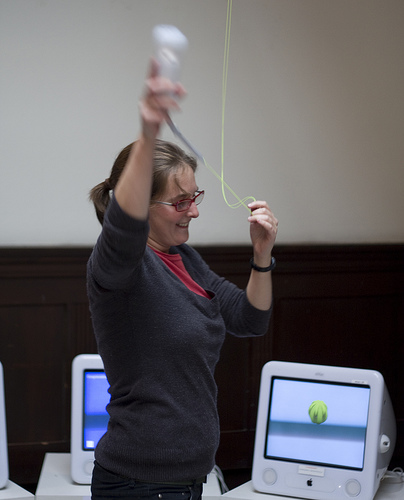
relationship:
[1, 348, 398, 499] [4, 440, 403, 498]
computer on desk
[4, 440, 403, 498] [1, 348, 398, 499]
desk under computer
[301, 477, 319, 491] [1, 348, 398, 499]
logo on computer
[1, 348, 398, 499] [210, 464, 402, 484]
computer has cord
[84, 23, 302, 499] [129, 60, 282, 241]
woman has hand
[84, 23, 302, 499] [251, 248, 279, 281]
woman has watch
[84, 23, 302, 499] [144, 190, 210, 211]
woman wearing glasses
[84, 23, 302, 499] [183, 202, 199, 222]
woman has nose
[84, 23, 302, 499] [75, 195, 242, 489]
woman wearing shirt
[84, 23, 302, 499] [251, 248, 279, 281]
woman wearing watch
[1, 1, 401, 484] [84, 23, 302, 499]
wall behind woman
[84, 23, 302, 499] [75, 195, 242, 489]
woman in shirt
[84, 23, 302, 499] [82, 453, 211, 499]
woman in jeans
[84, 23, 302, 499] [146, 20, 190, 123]
woman holding remote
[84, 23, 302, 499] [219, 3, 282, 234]
woman holding string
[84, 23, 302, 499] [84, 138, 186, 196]
woman has hair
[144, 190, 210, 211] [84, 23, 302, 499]
glasses on woman